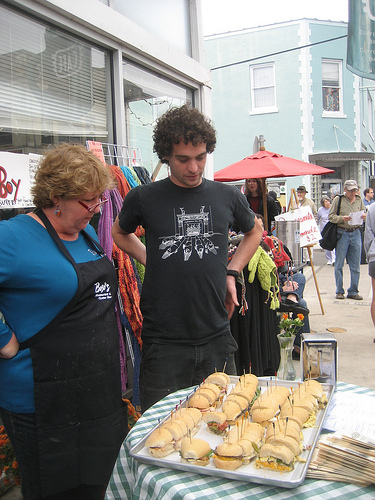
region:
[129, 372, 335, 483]
A silver pan.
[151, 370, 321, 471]
Sub sandwiches sliced up.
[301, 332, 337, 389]
A silver napkin dispenser.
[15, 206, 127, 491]
A black apron.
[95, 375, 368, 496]
A green and white tablecloth.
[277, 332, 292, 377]
A clear flower vase.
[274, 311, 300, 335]
Two orange flowers.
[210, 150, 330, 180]
A red umbrella.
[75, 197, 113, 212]
A pair of red framed glasses.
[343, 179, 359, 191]
A beige colored ball cap.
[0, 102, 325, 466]
A man and woman looking at sandwiches.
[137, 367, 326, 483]
The sandwiches are sitting on a tray.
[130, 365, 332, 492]
The tray is sitting ontop of a checkered cloth.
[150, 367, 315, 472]
There are toothpicks in the top of the sandwiches.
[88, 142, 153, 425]
There is a rack with scarves behind the man.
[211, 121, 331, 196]
There is a red umbrella.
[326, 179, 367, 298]
There is a man looking at a paper.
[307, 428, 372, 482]
A pile of napkins on the table.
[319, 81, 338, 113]
There is a person looking out of a window.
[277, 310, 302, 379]
A glass vase with two flowers in it.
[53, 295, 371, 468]
sandwiches on a platter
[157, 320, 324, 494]
sandwiches on a paper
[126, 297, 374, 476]
sandwiches with toothpicks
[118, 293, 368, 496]
toothpicks place in sandwiches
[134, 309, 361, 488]
small sandwiches on a platter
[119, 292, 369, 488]
sandwiches on a metal patter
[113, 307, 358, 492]
a silver platter on a table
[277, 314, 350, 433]
a napkin dispenser on the table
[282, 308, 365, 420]
a napkin dispers next to sandwiches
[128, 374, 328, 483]
Sub sandwich samples held together with toothpicks.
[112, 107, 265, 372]
Curly-haired man in black.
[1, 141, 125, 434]
Lady in blue, wearing glasses.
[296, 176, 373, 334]
Pedestrians at a street fair.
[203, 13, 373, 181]
Old fashioned blue and white building.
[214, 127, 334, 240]
Red shade umbrella.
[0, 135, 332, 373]
Booths and vendors at a street fair.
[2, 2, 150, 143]
Two tall windows.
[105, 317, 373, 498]
Table at a street fair.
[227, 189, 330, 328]
Booths at a street fair.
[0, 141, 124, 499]
Middle-aged woman who works for a restaurant called Bob's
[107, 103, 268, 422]
Young man wearing a black t-shirt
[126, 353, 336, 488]
Small sandwiches available for people to eat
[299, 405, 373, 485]
Napkins on the table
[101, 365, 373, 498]
Round table with green and white checkered tablecloth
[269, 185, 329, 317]
Sign on an easel, indicating items for sale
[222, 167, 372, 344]
Surrounding people at a marketplace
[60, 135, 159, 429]
Rack of clothes on display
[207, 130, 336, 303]
Umbrella for shade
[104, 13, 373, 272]
Two-story, blue with white trim building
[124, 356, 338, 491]
silver tray of sandwiches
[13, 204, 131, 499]
black apron on woman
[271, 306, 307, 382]
clear glass with orange flowers on it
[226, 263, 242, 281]
black wrist band on person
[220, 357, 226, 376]
toothpick in sandwich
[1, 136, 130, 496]
woman in blue shirt and black apron in front of sandwiches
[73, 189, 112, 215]
red framed glasses on woman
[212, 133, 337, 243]
red open umbrella on sidewalk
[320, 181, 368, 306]
a man with a black messenger bag.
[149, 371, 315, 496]
A silver pan.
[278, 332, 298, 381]
A clear white flower vase